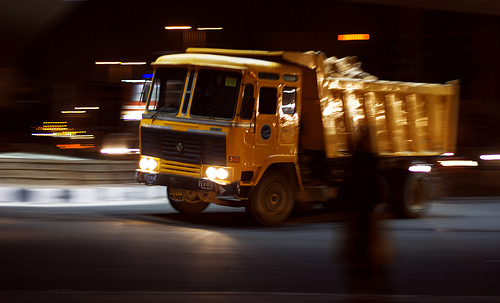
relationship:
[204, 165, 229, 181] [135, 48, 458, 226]
headlight on bus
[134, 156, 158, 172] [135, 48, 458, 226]
headlight on bus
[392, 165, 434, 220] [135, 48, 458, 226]
rear tire on bus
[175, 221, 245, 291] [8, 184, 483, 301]
reflection on pavement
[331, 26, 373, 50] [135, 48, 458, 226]
light over bus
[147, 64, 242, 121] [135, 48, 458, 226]
windshield on front of bus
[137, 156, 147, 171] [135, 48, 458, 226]
light on bus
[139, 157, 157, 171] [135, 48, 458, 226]
light on bus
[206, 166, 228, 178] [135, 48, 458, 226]
light on bus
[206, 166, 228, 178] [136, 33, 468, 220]
light on bus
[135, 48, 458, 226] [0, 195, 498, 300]
bus on street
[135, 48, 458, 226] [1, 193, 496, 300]
bus driving on road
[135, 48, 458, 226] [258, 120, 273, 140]
bus has decal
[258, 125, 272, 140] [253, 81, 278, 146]
decal on door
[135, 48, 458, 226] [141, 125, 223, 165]
bus has grill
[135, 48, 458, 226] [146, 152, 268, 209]
bus has four lights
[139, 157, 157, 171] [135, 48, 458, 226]
light of bus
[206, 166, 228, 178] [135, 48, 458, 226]
light of bus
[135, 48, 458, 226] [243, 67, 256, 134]
bus has arm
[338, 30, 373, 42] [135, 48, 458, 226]
orange light above bus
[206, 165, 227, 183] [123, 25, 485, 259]
light on truck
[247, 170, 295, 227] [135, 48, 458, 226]
tire on bus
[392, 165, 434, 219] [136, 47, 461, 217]
rear tire on truck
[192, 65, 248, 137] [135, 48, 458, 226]
window on bus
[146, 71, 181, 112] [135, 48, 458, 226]
window on bus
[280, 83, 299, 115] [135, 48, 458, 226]
window on bus